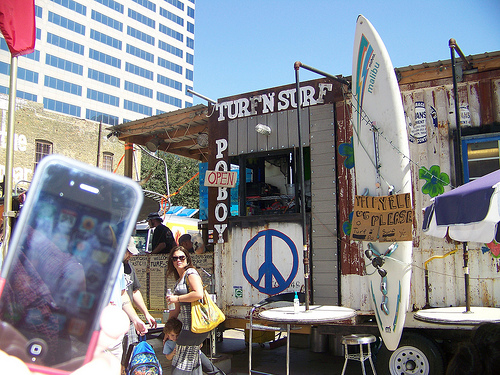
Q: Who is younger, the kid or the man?
A: The kid is younger than the man.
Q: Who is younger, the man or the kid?
A: The kid is younger than the man.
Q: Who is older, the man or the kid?
A: The man is older than the kid.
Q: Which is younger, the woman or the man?
A: The woman is younger than the man.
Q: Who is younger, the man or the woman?
A: The woman is younger than the man.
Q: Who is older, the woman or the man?
A: The man is older than the woman.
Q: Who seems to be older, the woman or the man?
A: The man is older than the woman.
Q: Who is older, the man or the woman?
A: The man is older than the woman.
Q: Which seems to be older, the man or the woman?
A: The man is older than the woman.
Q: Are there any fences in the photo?
A: No, there are no fences.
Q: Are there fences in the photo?
A: No, there are no fences.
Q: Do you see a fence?
A: No, there are no fences.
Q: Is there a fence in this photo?
A: No, there are no fences.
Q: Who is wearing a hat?
A: The man is wearing a hat.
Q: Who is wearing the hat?
A: The man is wearing a hat.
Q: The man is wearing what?
A: The man is wearing a hat.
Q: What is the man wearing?
A: The man is wearing a hat.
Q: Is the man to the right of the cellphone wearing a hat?
A: Yes, the man is wearing a hat.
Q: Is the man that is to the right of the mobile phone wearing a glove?
A: No, the man is wearing a hat.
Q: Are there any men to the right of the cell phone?
A: Yes, there is a man to the right of the cell phone.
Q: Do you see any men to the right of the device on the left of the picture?
A: Yes, there is a man to the right of the cell phone.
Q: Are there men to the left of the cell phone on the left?
A: No, the man is to the right of the mobile phone.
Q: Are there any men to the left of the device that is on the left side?
A: No, the man is to the right of the mobile phone.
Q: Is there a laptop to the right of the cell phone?
A: No, there is a man to the right of the cell phone.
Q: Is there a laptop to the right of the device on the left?
A: No, there is a man to the right of the cell phone.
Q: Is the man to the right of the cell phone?
A: Yes, the man is to the right of the cell phone.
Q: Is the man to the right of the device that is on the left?
A: Yes, the man is to the right of the cell phone.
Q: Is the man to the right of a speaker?
A: No, the man is to the right of the cell phone.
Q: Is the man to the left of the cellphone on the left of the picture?
A: No, the man is to the right of the cell phone.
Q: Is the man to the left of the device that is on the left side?
A: No, the man is to the right of the cell phone.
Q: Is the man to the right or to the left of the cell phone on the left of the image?
A: The man is to the right of the cell phone.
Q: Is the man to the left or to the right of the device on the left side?
A: The man is to the right of the cell phone.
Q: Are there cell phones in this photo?
A: Yes, there is a cell phone.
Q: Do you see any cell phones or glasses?
A: Yes, there is a cell phone.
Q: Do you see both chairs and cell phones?
A: No, there is a cell phone but no chairs.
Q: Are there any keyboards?
A: No, there are no keyboards.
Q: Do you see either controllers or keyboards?
A: No, there are no keyboards or controllers.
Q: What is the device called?
A: The device is a cell phone.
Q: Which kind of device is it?
A: The device is a cell phone.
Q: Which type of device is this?
A: This is a cell phone.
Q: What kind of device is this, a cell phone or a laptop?
A: This is a cell phone.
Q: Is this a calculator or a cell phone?
A: This is a cell phone.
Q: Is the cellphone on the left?
A: Yes, the cellphone is on the left of the image.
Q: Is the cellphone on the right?
A: No, the cellphone is on the left of the image.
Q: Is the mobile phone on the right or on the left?
A: The mobile phone is on the left of the image.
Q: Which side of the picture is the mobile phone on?
A: The mobile phone is on the left of the image.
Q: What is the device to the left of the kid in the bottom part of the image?
A: The device is a cell phone.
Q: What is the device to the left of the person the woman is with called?
A: The device is a cell phone.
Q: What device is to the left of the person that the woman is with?
A: The device is a cell phone.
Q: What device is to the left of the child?
A: The device is a cell phone.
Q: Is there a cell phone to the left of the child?
A: Yes, there is a cell phone to the left of the child.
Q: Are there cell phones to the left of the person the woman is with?
A: Yes, there is a cell phone to the left of the child.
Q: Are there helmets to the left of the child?
A: No, there is a cell phone to the left of the child.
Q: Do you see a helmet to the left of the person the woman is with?
A: No, there is a cell phone to the left of the child.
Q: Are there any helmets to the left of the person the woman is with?
A: No, there is a cell phone to the left of the child.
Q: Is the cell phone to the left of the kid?
A: Yes, the cell phone is to the left of the kid.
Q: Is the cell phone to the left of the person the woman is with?
A: Yes, the cell phone is to the left of the kid.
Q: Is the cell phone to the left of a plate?
A: No, the cell phone is to the left of the kid.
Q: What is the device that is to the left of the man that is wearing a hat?
A: The device is a cell phone.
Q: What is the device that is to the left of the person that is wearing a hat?
A: The device is a cell phone.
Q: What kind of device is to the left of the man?
A: The device is a cell phone.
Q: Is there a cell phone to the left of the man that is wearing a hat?
A: Yes, there is a cell phone to the left of the man.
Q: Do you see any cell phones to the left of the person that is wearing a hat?
A: Yes, there is a cell phone to the left of the man.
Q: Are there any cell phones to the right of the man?
A: No, the cell phone is to the left of the man.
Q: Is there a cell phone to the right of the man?
A: No, the cell phone is to the left of the man.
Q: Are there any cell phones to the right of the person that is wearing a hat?
A: No, the cell phone is to the left of the man.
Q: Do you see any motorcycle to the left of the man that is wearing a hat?
A: No, there is a cell phone to the left of the man.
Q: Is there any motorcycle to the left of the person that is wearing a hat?
A: No, there is a cell phone to the left of the man.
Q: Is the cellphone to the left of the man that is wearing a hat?
A: Yes, the cellphone is to the left of the man.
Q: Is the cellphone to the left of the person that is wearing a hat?
A: Yes, the cellphone is to the left of the man.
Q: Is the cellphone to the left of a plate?
A: No, the cellphone is to the left of the man.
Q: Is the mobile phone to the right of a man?
A: No, the mobile phone is to the left of a man.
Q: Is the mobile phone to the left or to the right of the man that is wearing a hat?
A: The mobile phone is to the left of the man.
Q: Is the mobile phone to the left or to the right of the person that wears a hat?
A: The mobile phone is to the left of the man.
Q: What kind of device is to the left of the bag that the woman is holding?
A: The device is a cell phone.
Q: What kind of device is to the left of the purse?
A: The device is a cell phone.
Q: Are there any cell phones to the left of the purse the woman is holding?
A: Yes, there is a cell phone to the left of the purse.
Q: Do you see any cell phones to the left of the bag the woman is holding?
A: Yes, there is a cell phone to the left of the purse.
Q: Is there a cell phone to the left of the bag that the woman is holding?
A: Yes, there is a cell phone to the left of the purse.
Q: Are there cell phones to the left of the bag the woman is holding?
A: Yes, there is a cell phone to the left of the purse.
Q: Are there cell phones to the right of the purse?
A: No, the cell phone is to the left of the purse.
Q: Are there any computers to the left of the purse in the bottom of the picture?
A: No, there is a cell phone to the left of the purse.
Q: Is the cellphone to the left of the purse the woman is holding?
A: Yes, the cellphone is to the left of the purse.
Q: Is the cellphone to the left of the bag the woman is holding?
A: Yes, the cellphone is to the left of the purse.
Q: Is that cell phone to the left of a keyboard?
A: No, the cell phone is to the left of the purse.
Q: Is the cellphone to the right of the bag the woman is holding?
A: No, the cellphone is to the left of the purse.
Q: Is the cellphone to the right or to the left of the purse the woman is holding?
A: The cellphone is to the left of the purse.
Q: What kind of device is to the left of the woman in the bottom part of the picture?
A: The device is a cell phone.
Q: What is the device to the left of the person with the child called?
A: The device is a cell phone.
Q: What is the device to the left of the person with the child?
A: The device is a cell phone.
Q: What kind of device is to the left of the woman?
A: The device is a cell phone.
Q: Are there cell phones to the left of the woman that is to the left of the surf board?
A: Yes, there is a cell phone to the left of the woman.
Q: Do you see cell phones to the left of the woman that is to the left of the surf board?
A: Yes, there is a cell phone to the left of the woman.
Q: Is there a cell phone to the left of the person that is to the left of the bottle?
A: Yes, there is a cell phone to the left of the woman.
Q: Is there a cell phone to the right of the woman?
A: No, the cell phone is to the left of the woman.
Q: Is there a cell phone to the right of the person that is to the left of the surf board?
A: No, the cell phone is to the left of the woman.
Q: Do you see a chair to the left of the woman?
A: No, there is a cell phone to the left of the woman.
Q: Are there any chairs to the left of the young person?
A: No, there is a cell phone to the left of the woman.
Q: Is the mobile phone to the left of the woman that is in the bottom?
A: Yes, the mobile phone is to the left of the woman.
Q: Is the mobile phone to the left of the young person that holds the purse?
A: Yes, the mobile phone is to the left of the woman.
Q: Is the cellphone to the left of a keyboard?
A: No, the cellphone is to the left of the woman.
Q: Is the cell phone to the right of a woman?
A: No, the cell phone is to the left of a woman.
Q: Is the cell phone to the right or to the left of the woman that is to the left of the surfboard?
A: The cell phone is to the left of the woman.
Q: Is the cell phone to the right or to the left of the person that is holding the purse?
A: The cell phone is to the left of the woman.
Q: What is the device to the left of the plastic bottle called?
A: The device is a cell phone.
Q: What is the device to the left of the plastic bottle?
A: The device is a cell phone.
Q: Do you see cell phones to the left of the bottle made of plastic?
A: Yes, there is a cell phone to the left of the bottle.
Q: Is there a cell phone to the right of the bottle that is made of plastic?
A: No, the cell phone is to the left of the bottle.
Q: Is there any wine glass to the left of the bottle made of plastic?
A: No, there is a cell phone to the left of the bottle.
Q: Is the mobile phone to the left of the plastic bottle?
A: Yes, the mobile phone is to the left of the bottle.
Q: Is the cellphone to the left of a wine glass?
A: No, the cellphone is to the left of the bottle.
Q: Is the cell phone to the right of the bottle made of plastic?
A: No, the cell phone is to the left of the bottle.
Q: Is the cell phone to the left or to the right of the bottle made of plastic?
A: The cell phone is to the left of the bottle.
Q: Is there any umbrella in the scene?
A: Yes, there is an umbrella.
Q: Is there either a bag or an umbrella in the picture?
A: Yes, there is an umbrella.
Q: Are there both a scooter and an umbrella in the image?
A: No, there is an umbrella but no scooters.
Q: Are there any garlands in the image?
A: No, there are no garlands.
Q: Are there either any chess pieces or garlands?
A: No, there are no garlands or chess pieces.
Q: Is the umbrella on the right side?
A: Yes, the umbrella is on the right of the image.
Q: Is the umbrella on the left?
A: No, the umbrella is on the right of the image.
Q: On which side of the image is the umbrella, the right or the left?
A: The umbrella is on the right of the image.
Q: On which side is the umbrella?
A: The umbrella is on the right of the image.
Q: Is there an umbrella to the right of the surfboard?
A: Yes, there is an umbrella to the right of the surfboard.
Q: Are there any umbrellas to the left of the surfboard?
A: No, the umbrella is to the right of the surfboard.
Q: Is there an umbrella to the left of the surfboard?
A: No, the umbrella is to the right of the surfboard.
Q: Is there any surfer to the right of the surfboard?
A: No, there is an umbrella to the right of the surfboard.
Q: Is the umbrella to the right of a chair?
A: No, the umbrella is to the right of the surfboard.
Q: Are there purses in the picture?
A: Yes, there is a purse.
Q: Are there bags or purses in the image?
A: Yes, there is a purse.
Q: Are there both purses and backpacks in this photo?
A: Yes, there are both a purse and a backpack.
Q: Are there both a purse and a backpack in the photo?
A: Yes, there are both a purse and a backpack.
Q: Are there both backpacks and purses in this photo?
A: Yes, there are both a purse and a backpack.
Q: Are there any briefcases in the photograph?
A: No, there are no briefcases.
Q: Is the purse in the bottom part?
A: Yes, the purse is in the bottom of the image.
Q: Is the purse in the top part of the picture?
A: No, the purse is in the bottom of the image.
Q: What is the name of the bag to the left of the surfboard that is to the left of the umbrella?
A: The bag is a purse.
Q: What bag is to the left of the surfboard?
A: The bag is a purse.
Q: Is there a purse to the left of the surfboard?
A: Yes, there is a purse to the left of the surfboard.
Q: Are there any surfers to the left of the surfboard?
A: No, there is a purse to the left of the surfboard.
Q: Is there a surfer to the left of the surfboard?
A: No, there is a purse to the left of the surfboard.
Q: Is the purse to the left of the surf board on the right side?
A: Yes, the purse is to the left of the surf board.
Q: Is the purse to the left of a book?
A: No, the purse is to the left of the surf board.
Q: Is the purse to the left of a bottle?
A: Yes, the purse is to the left of a bottle.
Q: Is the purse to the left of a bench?
A: No, the purse is to the left of a bottle.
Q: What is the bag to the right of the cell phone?
A: The bag is a purse.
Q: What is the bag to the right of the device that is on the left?
A: The bag is a purse.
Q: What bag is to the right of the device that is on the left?
A: The bag is a purse.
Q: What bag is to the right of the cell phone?
A: The bag is a purse.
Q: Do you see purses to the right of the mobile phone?
A: Yes, there is a purse to the right of the mobile phone.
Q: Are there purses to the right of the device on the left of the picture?
A: Yes, there is a purse to the right of the mobile phone.